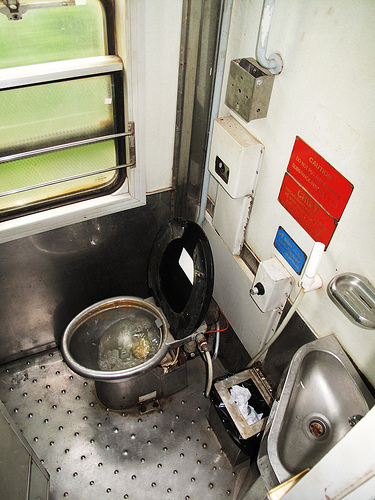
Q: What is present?
A: A toilet seat.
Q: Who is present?
A: Nobody.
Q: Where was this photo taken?
A: IN a bathroom.